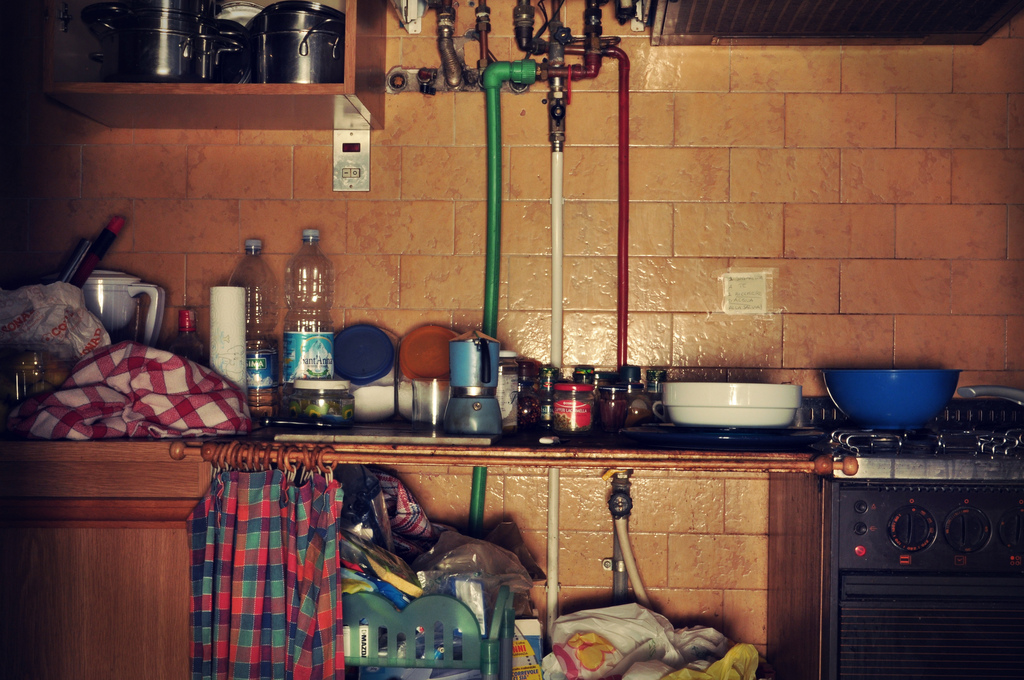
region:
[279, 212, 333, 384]
clear bottle on the counter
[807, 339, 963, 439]
blue bowl on top of the stove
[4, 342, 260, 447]
red and white checkered cloth on the counter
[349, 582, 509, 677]
basket full of garbage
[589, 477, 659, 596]
hoses coming out of the wall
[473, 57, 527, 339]
green water pipe connected to pipe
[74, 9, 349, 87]
silver pots on the shelf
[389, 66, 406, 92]
valve on the pipe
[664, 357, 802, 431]
white bowl on top of the counter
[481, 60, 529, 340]
green paint on the pipe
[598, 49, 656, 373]
redpaint on the pipe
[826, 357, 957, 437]
large blue bowl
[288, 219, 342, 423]
tall, clear, plastic bottle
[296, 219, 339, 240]
cap on the bottle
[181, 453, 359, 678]
red and green checker pattern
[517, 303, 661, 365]
light glare on the wall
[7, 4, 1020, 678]
the wall is tiled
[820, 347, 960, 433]
blue bowl on the stove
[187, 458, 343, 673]
checkered curtain hanging from a bar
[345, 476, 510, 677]
waste basket full of garbage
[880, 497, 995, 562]
knobs on the front of the stove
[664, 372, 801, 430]
white bowl on the counter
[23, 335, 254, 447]
red and white checkered cloth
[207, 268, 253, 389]
roll of paper towel on the counter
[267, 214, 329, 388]
clear plastic bottle on the counter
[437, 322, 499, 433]
coffee pot on the counter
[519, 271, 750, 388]
A person eating a orange.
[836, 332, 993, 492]
a bowl on the stove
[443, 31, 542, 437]
green pipe on the wall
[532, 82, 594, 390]
white pipe on the wall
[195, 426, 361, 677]
curtain on a pole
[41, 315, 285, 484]
a red and white fabric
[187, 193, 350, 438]
a pair of bottles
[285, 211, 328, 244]
blue top on bottle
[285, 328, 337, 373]
blue label on bottle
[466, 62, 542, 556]
a green colored supply pipe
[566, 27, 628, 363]
a red supply pipe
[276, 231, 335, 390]
bottle of vegetable oil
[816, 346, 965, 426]
blue plastic bowl on a stove top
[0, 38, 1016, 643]
glazed stone block wall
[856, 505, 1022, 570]
knobs on the cooking range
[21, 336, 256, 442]
red and white checked cloth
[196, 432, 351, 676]
red green and blue plaid curtain pulled back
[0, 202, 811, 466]
cluttered counter top beside a stove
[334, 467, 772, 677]
cluttered mess under the wood counter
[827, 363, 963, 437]
blue serving bowl on top of stove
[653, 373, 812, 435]
white bowl on counter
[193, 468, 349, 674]
coloful curtain for hiding cluttered compartment under sink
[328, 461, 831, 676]
apartment under sink cluttered with junk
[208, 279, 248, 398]
roll of white paper towels on counter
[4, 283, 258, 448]
wadded cloth sitting on counter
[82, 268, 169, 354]
blender container on counter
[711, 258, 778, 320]
small notice taped to wall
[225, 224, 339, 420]
two bottles of drinking water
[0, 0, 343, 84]
collection of pans on shelf